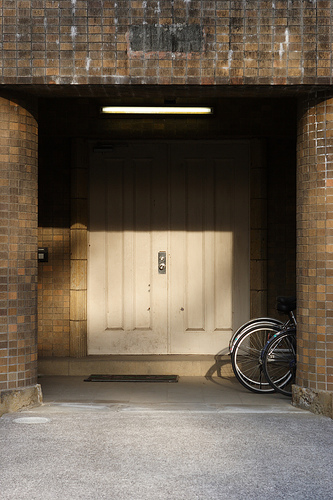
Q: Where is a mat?
A: On the ground.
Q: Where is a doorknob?
A: On the door.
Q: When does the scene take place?
A: During the daytime.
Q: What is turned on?
A: Light above door.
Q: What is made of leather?
A: Bicycle seats.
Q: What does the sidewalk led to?
A: House.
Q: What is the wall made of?
A: Brick.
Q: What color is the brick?
A: Orange.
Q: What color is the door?
A: White.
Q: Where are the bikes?
A: Next to the door.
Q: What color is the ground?
A: Gray.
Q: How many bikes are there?
A: Three.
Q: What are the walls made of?
A: Brick.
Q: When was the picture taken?
A: Daytime.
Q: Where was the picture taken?
A: In Paris.